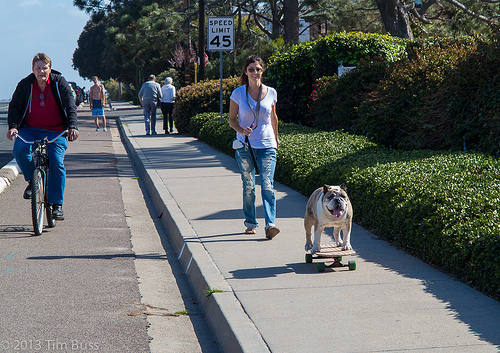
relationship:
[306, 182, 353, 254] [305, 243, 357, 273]
dog riding skateboar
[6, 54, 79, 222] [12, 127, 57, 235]
man on bike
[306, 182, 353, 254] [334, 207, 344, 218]
dog has a tongue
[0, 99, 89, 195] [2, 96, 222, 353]
curb on road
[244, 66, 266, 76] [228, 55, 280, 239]
sunglasses on woman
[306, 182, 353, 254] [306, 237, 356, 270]
dog riding skateboard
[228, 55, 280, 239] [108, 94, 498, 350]
woman on sidewalk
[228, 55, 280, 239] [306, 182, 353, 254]
woman and dog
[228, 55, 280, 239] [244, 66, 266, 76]
woman wearing sunglasses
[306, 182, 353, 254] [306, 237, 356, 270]
dog riding on skateboard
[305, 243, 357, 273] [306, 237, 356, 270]
wheels under skateboard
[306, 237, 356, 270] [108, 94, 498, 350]
skateboard on sidewalk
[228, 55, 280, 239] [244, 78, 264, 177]
woman has a leash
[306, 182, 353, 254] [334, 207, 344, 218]
dog sticking out h tongue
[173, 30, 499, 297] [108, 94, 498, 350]
bushes near sidewalk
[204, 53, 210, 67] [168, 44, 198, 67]
sign near flowers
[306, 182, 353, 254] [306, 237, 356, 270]
dog on skateboard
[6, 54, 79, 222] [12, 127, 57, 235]
man riding h bike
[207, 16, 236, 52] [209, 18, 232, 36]
sign says speed limit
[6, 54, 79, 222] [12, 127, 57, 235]
man on h bike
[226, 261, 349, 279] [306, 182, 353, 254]
shadow from dog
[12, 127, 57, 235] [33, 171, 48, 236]
bike has a front tire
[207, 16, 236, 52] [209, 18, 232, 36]
sign for speed limit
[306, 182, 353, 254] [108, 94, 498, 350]
dog on sidewalk